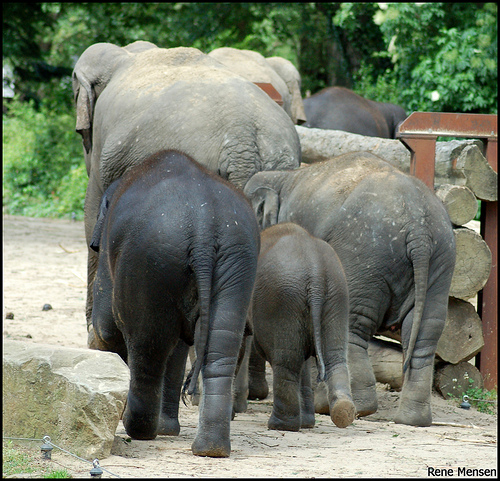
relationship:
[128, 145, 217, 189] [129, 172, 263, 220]
hair on back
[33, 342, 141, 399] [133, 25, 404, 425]
rock needs elephants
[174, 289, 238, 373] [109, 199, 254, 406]
tails of elephant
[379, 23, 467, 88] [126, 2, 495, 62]
foilage in background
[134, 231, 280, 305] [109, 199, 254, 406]
rump of elephant